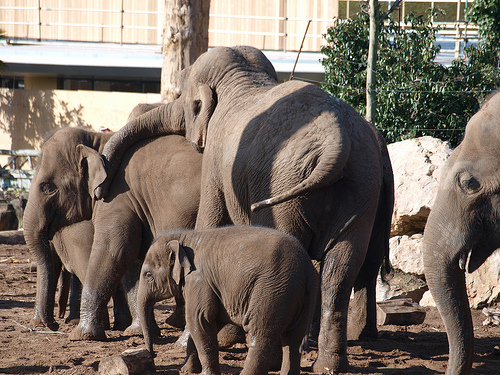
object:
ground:
[0, 244, 499, 375]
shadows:
[362, 330, 499, 375]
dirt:
[348, 324, 498, 375]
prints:
[72, 362, 103, 373]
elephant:
[21, 128, 203, 341]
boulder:
[385, 134, 453, 237]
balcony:
[0, 0, 499, 77]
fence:
[0, 0, 499, 59]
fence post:
[367, 0, 376, 122]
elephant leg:
[282, 310, 310, 372]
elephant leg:
[184, 289, 219, 369]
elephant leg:
[317, 237, 368, 356]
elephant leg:
[78, 209, 141, 325]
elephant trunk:
[422, 189, 476, 374]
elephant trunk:
[136, 287, 158, 359]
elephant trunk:
[91, 101, 185, 200]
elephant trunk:
[22, 202, 58, 331]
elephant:
[92, 44, 381, 375]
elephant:
[136, 226, 319, 375]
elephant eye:
[145, 272, 153, 280]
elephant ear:
[76, 144, 107, 200]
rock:
[96, 346, 156, 375]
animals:
[22, 46, 499, 374]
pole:
[160, 0, 210, 106]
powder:
[76, 291, 101, 334]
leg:
[68, 215, 142, 341]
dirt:
[30, 341, 76, 365]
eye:
[459, 174, 483, 191]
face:
[451, 90, 500, 274]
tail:
[248, 140, 352, 212]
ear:
[164, 239, 191, 286]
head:
[134, 235, 182, 306]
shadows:
[1, 88, 91, 169]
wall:
[0, 89, 161, 169]